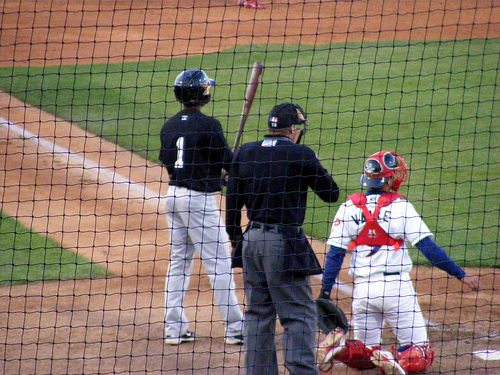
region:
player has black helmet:
[165, 50, 207, 102]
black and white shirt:
[150, 102, 207, 196]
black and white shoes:
[156, 329, 234, 348]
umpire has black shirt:
[225, 119, 300, 210]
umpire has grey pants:
[247, 225, 318, 372]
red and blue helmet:
[356, 130, 404, 192]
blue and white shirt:
[331, 199, 433, 307]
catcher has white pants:
[356, 257, 415, 358]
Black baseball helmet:
[171, 65, 218, 108]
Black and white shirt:
[157, 108, 234, 195]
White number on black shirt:
[171, 135, 186, 170]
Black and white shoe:
[165, 330, 197, 345]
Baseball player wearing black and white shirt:
[157, 68, 247, 345]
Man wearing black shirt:
[221, 100, 338, 373]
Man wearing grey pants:
[226, 101, 341, 373]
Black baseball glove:
[313, 295, 350, 335]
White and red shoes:
[311, 325, 346, 371]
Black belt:
[246, 219, 303, 236]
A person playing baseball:
[154, 18, 243, 370]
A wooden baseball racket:
[233, 56, 270, 152]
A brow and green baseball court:
[2, 6, 69, 148]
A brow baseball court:
[45, 159, 167, 235]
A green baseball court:
[417, 98, 497, 221]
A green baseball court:
[323, 51, 459, 142]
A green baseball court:
[84, 68, 171, 114]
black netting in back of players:
[15, 11, 490, 362]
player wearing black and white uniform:
[160, 56, 241, 343]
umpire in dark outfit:
[221, 90, 336, 370]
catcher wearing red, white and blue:
[317, 145, 467, 370]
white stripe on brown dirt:
[0, 97, 165, 269]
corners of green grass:
[0, 40, 150, 290]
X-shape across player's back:
[347, 190, 402, 251]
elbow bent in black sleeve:
[302, 142, 337, 202]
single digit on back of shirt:
[157, 110, 222, 185]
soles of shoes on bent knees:
[317, 327, 435, 370]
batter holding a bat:
[153, 37, 270, 347]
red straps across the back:
[342, 195, 407, 252]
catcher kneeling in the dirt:
[313, 135, 482, 373]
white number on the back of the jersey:
[166, 128, 196, 177]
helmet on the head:
[166, 65, 218, 102]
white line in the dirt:
[0, 101, 182, 226]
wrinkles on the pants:
[188, 204, 226, 280]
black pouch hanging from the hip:
[278, 223, 328, 280]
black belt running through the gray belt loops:
[246, 218, 278, 231]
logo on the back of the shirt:
[259, 138, 279, 147]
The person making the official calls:
[216, 100, 351, 373]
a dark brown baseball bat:
[230, 62, 262, 147]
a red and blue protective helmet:
[358, 150, 405, 188]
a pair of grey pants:
[241, 224, 316, 374]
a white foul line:
[0, 117, 165, 204]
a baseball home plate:
[471, 349, 499, 361]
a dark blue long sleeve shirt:
[225, 137, 339, 244]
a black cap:
[265, 102, 306, 129]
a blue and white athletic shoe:
[164, 330, 198, 345]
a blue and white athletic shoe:
[222, 333, 243, 342]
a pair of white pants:
[351, 279, 427, 351]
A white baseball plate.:
[465, 341, 496, 362]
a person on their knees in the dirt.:
[317, 130, 467, 372]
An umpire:
[207, 101, 347, 361]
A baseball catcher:
[320, 137, 470, 367]